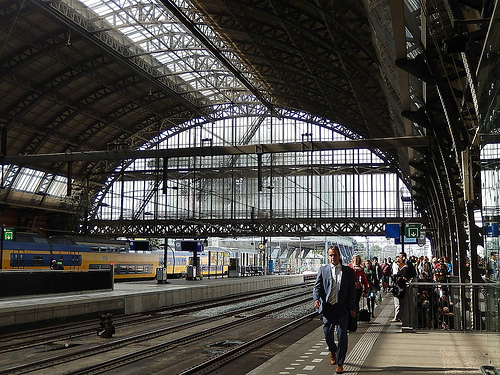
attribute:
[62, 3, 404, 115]
roof — domed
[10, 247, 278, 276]
train — blue, yellow, waiting, commuter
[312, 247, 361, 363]
man — walking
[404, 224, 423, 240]
sign — green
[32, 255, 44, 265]
window — large, long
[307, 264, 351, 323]
suit — blue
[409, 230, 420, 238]
arrow — white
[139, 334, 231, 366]
tracks — several, empty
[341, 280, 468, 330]
people — group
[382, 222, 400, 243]
flag — blue, hanging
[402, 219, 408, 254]
pole — black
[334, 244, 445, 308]
people — many, walking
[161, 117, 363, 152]
bars — metal, curved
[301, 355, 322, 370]
squares — white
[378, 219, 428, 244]
signs — blue, green, hanging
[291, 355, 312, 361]
lines — white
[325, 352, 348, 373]
shoes — brown